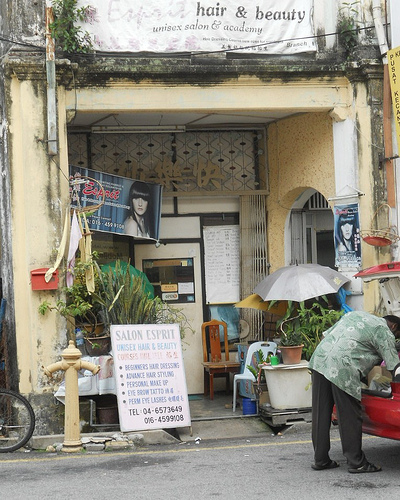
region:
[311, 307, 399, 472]
Man bending over car trunk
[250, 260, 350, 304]
Gray to silver umbrella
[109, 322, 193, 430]
Salon Hair and Beauty Sign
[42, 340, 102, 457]
Yellow T Style Firehydrant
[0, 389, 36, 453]
Black Bike Tire and Spokes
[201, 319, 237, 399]
Old Brown Wooden Chair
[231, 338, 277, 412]
White Plastic Patio Chair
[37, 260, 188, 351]
Green Plants in Pots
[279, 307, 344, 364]
Green Plants in Pots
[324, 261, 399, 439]
Red Car Trunk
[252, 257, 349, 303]
gray umbrella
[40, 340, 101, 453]
painted fire hydrant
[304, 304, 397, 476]
man reaching into his trunk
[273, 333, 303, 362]
plant in pot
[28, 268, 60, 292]
mail receptacle on building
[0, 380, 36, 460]
bicycle tire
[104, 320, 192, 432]
street sign advertising salon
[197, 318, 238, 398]
wooden chair with high back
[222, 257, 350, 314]
two umbrellas side by side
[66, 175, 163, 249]
a banner hanging in front of the salo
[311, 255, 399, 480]
guy digging in truck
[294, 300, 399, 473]
guy wearing green shirt with flowers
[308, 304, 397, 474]
guy wearing grey pants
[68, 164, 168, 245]
girl on big sign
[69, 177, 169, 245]
girl on sign with bangs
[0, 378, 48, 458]
black bicycle wheel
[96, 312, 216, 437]
white store sign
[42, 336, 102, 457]
tall yellow fire hydrant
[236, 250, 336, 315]
yellow and grey umbrella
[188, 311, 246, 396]
brown wooden chair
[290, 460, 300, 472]
part of a road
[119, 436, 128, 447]
edge of a road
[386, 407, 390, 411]
back of a car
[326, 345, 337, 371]
back of a man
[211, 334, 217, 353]
part of a chair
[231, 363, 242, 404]
part of a chair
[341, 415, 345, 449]
part of a trouser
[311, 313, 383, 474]
person wearing a gree shirt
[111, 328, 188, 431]
an advertisement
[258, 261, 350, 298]
an umbrella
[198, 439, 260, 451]
yellow line on the ground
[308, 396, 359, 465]
person is wearing pants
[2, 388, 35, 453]
a bike tire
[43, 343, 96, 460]
a fire hydrant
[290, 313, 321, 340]
green leaves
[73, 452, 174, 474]
a stain on the ground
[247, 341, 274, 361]
the chair is white